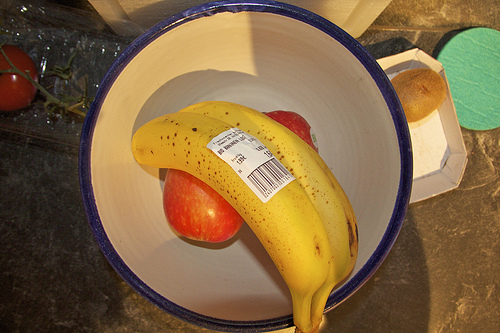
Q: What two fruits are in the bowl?
A: Bananas and apples.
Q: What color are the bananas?
A: Yellow.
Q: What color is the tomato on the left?
A: Red.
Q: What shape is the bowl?
A: Round.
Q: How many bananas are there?
A: Two.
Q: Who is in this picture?
A: No one.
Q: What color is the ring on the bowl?
A: Blue.